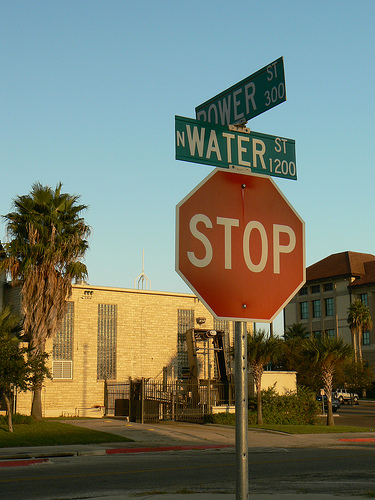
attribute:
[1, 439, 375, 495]
road — tarmac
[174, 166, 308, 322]
sign — giving directions, red, large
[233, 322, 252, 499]
pole — silver, metal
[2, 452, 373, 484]
lines — yellow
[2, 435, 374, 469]
paint — red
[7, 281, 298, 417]
building — short, tall, brick, white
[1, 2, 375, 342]
sky — blue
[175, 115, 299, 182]
sign — green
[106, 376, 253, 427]
gate — black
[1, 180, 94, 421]
palm tree — tall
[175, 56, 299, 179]
signs — green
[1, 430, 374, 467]
sidewalk — paved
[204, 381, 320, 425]
hedge — green